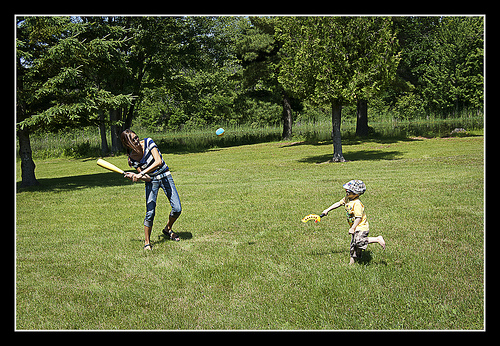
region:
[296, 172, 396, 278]
kid wearing protective head gear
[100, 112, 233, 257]
woman trying to hit ball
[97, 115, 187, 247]
woman holding a bat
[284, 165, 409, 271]
kid wearing yellow shirt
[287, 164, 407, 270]
kid wearing short pants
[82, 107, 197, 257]
woman wearing stripped shirts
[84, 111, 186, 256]
woman holding a baseball bat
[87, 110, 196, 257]
woman wearing blue jeans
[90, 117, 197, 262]
woman wearing sandals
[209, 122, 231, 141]
ball in mid air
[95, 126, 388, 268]
A woman playing t ball with a child.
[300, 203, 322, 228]
Holding a ball catching scoop.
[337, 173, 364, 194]
The boy is wearing a helmet.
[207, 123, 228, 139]
A blue ball in the air.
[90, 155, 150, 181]
The woman is holding a bat.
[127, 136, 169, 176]
woman in a black and white striped shirt.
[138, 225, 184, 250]
Woman wearing sandals.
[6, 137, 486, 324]
Green grass on the ground.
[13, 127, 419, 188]
Tree shadows on the grass.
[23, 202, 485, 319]
grasses are green in color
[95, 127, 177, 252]
a woman holding a bat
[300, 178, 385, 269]
a kid wearing a glove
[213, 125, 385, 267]
a kid is pitching a ball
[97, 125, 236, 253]
a woman getting ready to hit the ball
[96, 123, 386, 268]
a woman and a kid are playing the base ball game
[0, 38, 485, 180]
well grown trees with branches of green leaves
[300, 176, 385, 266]
a kid with a cap on his head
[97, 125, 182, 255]
a woman wearing blue color jeans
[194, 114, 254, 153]
a ball travelling in the air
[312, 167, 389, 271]
Small child in the grass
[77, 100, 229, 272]
Woman in the grass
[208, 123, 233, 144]
Blue and white ball in the air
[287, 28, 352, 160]
Large tree in a field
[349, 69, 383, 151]
Large tree in a field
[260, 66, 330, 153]
Large tree in a field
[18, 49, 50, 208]
Large tree in a field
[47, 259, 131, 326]
Patch of green grass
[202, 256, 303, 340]
Patch of green grass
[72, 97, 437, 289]
Mom and son playing outside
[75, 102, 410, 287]
Woman hitting ball to child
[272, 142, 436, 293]
Boy playing with toy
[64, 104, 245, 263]
Woman swinging at ball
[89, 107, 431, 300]
Boy throwing ball to woman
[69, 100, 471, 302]
Mom and son playing sport outside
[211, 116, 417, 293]
Little boy pitching ball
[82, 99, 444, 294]
Family members playing an outdoor sport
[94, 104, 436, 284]
Mom and son playing baseball in park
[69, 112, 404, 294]
Boy pitching ball to mother